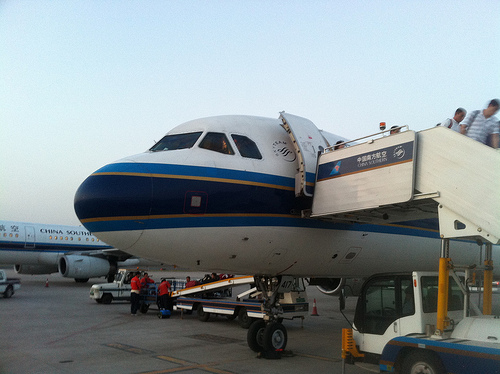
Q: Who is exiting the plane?
A: Passengers.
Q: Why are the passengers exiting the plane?
A: They arrived.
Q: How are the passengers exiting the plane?
A: On stairs.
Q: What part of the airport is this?
A: Runway.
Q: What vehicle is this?
A: Plane.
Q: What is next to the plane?
A: Another plane.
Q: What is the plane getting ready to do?
A: Take off.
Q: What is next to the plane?
A: Truck.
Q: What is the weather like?
A: Clear.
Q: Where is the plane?
A: Boarding gate.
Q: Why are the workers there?
A: Collect luggage.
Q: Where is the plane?
A: Airport.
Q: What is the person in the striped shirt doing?
A: Exiting plane.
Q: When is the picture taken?
A: Evening.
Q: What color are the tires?
A: Black.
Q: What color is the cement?
A: Grey.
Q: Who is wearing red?
A: Workers.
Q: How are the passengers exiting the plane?
A: Stairs.